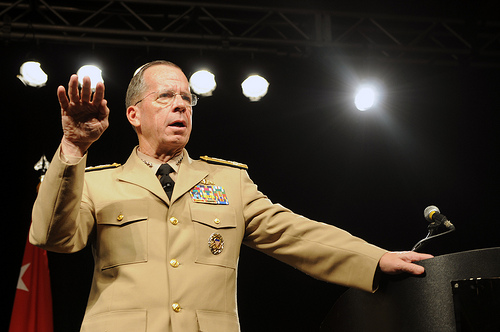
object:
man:
[27, 61, 434, 332]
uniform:
[28, 147, 386, 332]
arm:
[243, 168, 426, 294]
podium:
[372, 245, 499, 331]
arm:
[28, 73, 110, 252]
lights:
[355, 88, 376, 111]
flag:
[8, 157, 55, 331]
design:
[17, 263, 30, 292]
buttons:
[169, 217, 178, 225]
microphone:
[413, 205, 455, 252]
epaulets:
[197, 156, 249, 171]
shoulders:
[227, 162, 248, 173]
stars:
[149, 163, 153, 168]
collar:
[136, 148, 185, 176]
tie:
[156, 163, 176, 201]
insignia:
[208, 232, 224, 255]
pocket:
[190, 203, 239, 270]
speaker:
[451, 277, 498, 331]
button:
[214, 218, 221, 223]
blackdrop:
[282, 108, 490, 201]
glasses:
[155, 91, 199, 106]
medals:
[189, 179, 229, 206]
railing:
[0, 0, 499, 55]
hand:
[378, 251, 435, 274]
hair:
[125, 61, 180, 107]